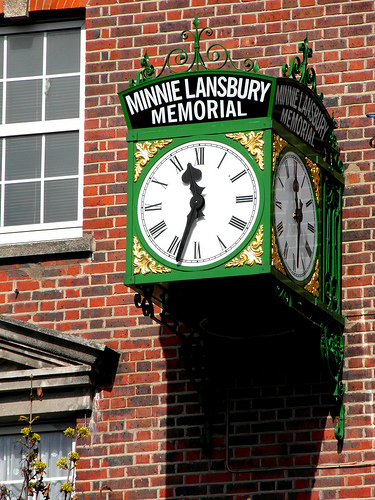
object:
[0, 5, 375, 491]
picture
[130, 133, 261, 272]
clock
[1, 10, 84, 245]
window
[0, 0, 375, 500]
building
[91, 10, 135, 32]
red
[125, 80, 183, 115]
minnie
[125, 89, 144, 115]
lettering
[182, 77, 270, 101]
lansbury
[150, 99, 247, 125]
memorial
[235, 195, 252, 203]
numerals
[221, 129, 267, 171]
design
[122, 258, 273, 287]
green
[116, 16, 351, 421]
item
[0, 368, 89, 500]
weeds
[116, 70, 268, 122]
sign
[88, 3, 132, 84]
wall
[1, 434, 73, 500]
curtains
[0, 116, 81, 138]
wood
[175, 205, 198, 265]
black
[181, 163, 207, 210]
short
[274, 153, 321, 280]
another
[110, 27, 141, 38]
brick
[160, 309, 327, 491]
shadow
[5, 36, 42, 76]
panes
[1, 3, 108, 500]
wall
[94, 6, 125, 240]
dark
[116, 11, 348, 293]
wall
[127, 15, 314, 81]
iron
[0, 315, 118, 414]
molding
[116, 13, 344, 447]
frame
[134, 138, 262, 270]
face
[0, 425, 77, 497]
window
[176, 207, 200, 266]
arm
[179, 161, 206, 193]
arm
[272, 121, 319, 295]
watch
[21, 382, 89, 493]
element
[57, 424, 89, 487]
flowers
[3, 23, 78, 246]
blinds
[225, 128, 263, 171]
leaves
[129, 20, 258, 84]
curliques